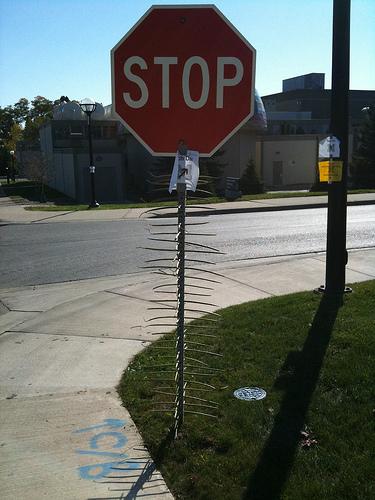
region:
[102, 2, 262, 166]
red and white stop sign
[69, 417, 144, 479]
blue graffiti on the ground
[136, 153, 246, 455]
spikes on the pole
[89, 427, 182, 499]
shaodw from the pole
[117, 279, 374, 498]
dark green grass on the ground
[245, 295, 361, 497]
shadow on the grass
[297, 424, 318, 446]
leaf on the grass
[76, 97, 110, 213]
black and white lamp post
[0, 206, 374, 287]
asphalt on the road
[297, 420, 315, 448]
leaves on the grass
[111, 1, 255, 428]
The stop sign has spikes in it.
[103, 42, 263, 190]
A white sign is under the stop sign.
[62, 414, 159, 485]
The sidewalk has blue letters.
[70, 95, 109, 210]
The lamp has a round bulb.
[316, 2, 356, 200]
The telephone pole has two papers.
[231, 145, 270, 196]
The tree is next to the building.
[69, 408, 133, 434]
The arrow is blue.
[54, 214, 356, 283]
The street has no cars.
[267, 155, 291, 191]
The door is closed.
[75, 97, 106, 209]
The lamp is black.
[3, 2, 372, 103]
blue of daytime sky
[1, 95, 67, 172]
green trees on horizon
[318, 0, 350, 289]
two papers on pole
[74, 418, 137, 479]
blue spray paint on sidewalk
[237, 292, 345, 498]
shadow of pole on grass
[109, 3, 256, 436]
stop sign on top of pole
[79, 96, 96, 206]
light on top of pole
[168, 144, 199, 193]
curled paper taped to sign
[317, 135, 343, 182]
white and yellow paper on pole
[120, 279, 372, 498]
green grass on corner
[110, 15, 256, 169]
red and white sign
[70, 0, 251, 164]
white letters on sign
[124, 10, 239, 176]
sign on grey pole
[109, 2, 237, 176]
sign is octagonal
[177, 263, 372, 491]
green grass beneath stop sign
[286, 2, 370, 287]
telephone pole near sidewalk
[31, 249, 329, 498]
sidewalk is light brown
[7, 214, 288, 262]
road is dark grey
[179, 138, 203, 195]
paper posted on sign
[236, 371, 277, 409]
water pipe next to stop sign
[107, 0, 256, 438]
stop sign on the grass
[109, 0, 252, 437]
stop sign is on the pole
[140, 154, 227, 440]
spikes are on the pole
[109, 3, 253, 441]
spikes are on the stop sign pole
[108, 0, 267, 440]
stop sign is on the corner of the street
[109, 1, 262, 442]
stop sign is by the sidewalk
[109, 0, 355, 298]
stop sign is in front of the street pole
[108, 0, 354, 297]
street pole is behind the stop sign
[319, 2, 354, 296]
street pole is on the grass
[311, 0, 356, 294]
street pole is by the sidewalk